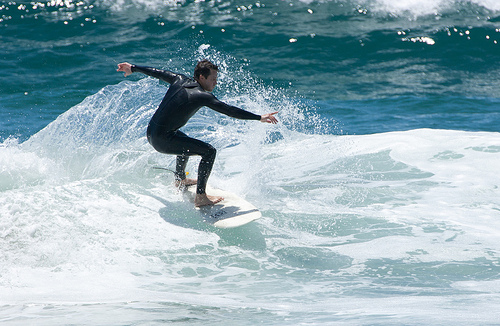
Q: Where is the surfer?
A: Ocean.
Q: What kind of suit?
A: Wetsuit.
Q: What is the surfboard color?
A: White.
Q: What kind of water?
A: Foamy.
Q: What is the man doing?
A: Surfing.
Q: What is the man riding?
A: Waves.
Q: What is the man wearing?
A: Wetsuit.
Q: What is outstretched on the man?
A: Arms.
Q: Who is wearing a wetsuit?
A: Man surfing.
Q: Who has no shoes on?
A: Surfer.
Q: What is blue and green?
A: Ocean.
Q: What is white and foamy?
A: Sea foam.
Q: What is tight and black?
A: Wet suit.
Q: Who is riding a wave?
A: Surfer.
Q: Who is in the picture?
A: A surfer.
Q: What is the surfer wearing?
A: A wetsuit.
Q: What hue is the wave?
A: White.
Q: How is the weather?
A: Sunny and clear.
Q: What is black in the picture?
A: A wet suit.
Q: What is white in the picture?
A: The surfboard.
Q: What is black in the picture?
A: The wet suit.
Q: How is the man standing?
A: With arms extended.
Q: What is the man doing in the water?
A: Surfing.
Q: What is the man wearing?
A: A wetsuit.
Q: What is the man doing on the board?
A: Standing.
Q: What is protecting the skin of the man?
A: A wetsuit.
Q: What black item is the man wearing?
A: A wetsuit.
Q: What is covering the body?
A: A wetsuit.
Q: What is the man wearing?
A: A wetsuit.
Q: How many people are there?
A: One.